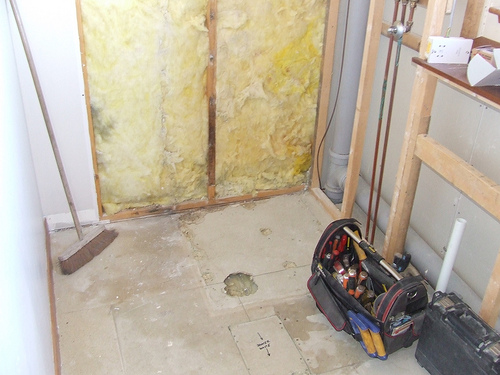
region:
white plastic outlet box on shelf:
[424, 31, 471, 67]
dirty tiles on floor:
[118, 216, 308, 362]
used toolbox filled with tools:
[306, 209, 423, 360]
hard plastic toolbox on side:
[411, 289, 495, 373]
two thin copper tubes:
[361, 0, 416, 256]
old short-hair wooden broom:
[6, 1, 121, 278]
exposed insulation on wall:
[224, 6, 306, 193]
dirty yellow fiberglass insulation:
[92, 9, 200, 196]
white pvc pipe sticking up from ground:
[429, 217, 471, 294]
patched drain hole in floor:
[215, 269, 260, 306]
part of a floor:
[183, 290, 215, 332]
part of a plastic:
[452, 217, 467, 242]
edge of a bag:
[339, 296, 366, 313]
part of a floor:
[230, 328, 252, 353]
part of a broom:
[75, 235, 107, 265]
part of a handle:
[58, 179, 70, 216]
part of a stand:
[386, 167, 409, 216]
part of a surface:
[220, 253, 254, 285]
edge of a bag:
[384, 288, 404, 334]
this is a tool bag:
[311, 235, 426, 340]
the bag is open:
[320, 237, 407, 312]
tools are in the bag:
[345, 257, 372, 284]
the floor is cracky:
[219, 257, 268, 305]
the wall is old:
[139, 6, 299, 173]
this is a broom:
[53, 217, 129, 265]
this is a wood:
[400, 129, 427, 168]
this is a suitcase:
[421, 319, 475, 360]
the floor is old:
[217, 218, 298, 246]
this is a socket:
[421, 40, 473, 61]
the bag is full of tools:
[297, 220, 444, 335]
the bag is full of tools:
[330, 251, 410, 342]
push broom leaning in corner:
[0, 3, 122, 280]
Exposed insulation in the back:
[74, 0, 330, 218]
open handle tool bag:
[302, 215, 429, 361]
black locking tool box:
[411, 283, 498, 374]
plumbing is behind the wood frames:
[313, 1, 497, 326]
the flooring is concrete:
[46, 190, 438, 374]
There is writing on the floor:
[252, 328, 278, 366]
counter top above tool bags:
[412, 36, 499, 120]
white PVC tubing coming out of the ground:
[433, 214, 467, 298]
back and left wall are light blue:
[0, 1, 98, 374]